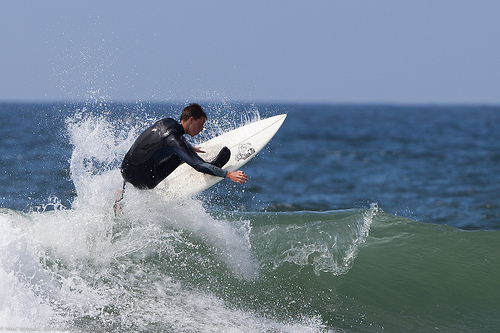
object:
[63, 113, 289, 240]
surfboard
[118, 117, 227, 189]
wetsuit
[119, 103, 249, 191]
surfer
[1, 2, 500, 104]
sky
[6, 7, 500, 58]
clouds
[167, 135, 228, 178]
arm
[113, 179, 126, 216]
cable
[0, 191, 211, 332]
wake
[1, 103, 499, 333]
water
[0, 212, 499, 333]
wave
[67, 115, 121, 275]
splash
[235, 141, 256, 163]
logo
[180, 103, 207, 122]
hair